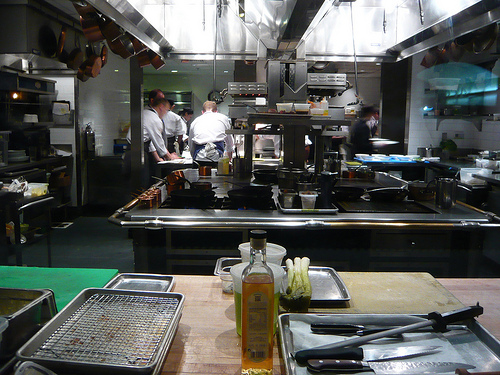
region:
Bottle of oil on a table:
[237, 228, 278, 373]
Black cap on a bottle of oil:
[249, 228, 264, 239]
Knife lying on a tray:
[306, 354, 475, 373]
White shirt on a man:
[188, 111, 235, 151]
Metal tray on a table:
[14, 289, 183, 371]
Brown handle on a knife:
[297, 357, 367, 371]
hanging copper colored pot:
[77, 9, 105, 46]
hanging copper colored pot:
[103, 19, 120, 44]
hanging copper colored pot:
[113, 37, 135, 63]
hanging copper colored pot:
[128, 34, 145, 55]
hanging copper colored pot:
[133, 50, 150, 70]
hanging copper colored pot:
[146, 48, 163, 74]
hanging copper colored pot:
[56, 25, 68, 58]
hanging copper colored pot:
[64, 46, 82, 70]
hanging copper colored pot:
[86, 55, 102, 82]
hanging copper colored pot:
[74, 60, 88, 82]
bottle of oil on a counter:
[236, 227, 278, 374]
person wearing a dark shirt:
[345, 98, 379, 158]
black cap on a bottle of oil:
[247, 222, 269, 239]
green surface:
[0, 257, 127, 319]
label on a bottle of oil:
[241, 288, 272, 368]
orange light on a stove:
[11, 90, 22, 100]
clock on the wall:
[207, 88, 226, 108]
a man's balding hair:
[150, 86, 161, 93]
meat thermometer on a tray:
[292, 297, 487, 356]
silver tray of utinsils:
[273, 305, 498, 373]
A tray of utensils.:
[294, 302, 487, 374]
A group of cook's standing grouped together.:
[137, 85, 229, 159]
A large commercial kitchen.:
[2, 0, 497, 373]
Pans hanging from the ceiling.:
[36, 19, 118, 81]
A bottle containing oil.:
[237, 228, 277, 373]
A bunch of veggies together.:
[283, 253, 313, 302]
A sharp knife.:
[305, 355, 476, 373]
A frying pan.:
[361, 181, 411, 201]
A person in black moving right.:
[349, 106, 377, 152]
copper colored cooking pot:
[53, 28, 72, 60]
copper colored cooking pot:
[67, 50, 86, 75]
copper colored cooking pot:
[82, 54, 102, 77]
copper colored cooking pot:
[99, 43, 109, 66]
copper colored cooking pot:
[76, 68, 91, 83]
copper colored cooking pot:
[146, 49, 163, 72]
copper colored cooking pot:
[131, 35, 146, 56]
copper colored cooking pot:
[80, 15, 105, 47]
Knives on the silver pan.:
[322, 305, 447, 373]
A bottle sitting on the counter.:
[232, 214, 279, 366]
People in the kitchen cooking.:
[138, 91, 230, 160]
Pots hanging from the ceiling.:
[36, 33, 106, 73]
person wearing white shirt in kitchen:
[123, 96, 181, 181]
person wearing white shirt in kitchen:
[144, 83, 185, 159]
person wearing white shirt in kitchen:
[187, 99, 235, 164]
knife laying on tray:
[307, 358, 476, 374]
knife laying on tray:
[294, 345, 441, 361]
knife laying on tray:
[310, 320, 452, 334]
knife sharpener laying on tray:
[289, 301, 482, 357]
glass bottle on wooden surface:
[240, 227, 274, 373]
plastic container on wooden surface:
[232, 262, 285, 338]